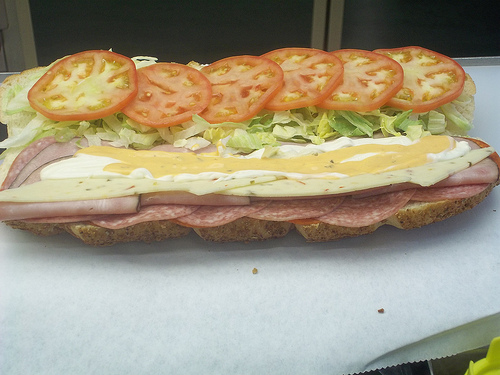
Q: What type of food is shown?
A: Sub sandwich.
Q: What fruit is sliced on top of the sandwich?
A: Tomatoes.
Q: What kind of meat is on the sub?
A: Ham and salami.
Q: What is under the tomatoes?
A: Lettuce.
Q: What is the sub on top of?
A: White paper.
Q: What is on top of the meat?
A: Cheese.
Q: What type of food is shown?
A: A sandwich.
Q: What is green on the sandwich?
A: Lettuce.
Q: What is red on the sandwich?
A: Tomatoes.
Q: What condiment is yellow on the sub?
A: Mustard.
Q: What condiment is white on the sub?
A: Mayonnaise.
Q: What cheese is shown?
A: Pepper jack.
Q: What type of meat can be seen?
A: Ham and pepperoni.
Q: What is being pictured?
A: A sandwich.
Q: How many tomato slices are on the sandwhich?
A: Six.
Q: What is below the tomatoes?
A: Lettuce.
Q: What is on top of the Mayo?
A: Mustard.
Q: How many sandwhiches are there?
A: One.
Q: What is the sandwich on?
A: Paper.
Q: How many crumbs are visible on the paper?
A: Three.